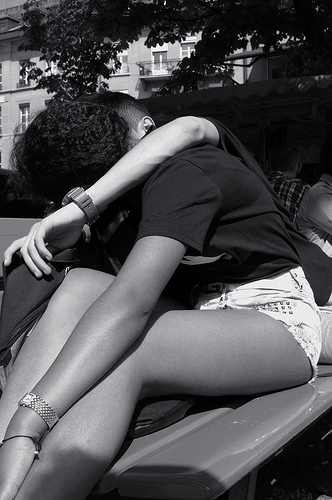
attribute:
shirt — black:
[126, 142, 305, 287]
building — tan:
[1, 2, 330, 196]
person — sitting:
[0, 94, 207, 392]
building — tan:
[1, 0, 327, 172]